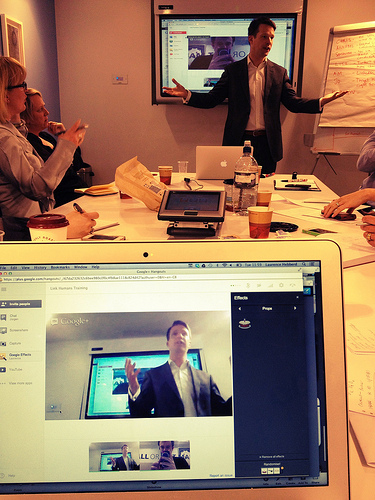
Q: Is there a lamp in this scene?
A: No, there are no lamps.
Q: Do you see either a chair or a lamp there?
A: No, there are no lamps or chairs.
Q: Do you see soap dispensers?
A: No, there are no soap dispensers.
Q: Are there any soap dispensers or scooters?
A: No, there are no soap dispensers or scooters.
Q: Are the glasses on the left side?
A: Yes, the glasses are on the left of the image.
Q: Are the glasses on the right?
A: No, the glasses are on the left of the image.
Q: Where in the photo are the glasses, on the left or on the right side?
A: The glasses are on the left of the image.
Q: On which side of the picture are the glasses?
A: The glasses are on the left of the image.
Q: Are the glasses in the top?
A: Yes, the glasses are in the top of the image.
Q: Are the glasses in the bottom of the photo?
A: No, the glasses are in the top of the image.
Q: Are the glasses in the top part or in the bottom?
A: The glasses are in the top of the image.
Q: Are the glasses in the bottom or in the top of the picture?
A: The glasses are in the top of the image.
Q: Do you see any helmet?
A: No, there are no helmets.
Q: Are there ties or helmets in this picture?
A: No, there are no helmets or ties.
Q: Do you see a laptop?
A: Yes, there is a laptop.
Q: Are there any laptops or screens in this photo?
A: Yes, there is a laptop.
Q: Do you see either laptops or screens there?
A: Yes, there is a laptop.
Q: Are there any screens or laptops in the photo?
A: Yes, there is a laptop.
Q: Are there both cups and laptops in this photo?
A: Yes, there are both a laptop and a cup.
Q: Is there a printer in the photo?
A: No, there are no printers.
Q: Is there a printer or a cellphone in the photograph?
A: No, there are no printers or cell phones.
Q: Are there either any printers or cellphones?
A: No, there are no printers or cellphones.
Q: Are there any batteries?
A: No, there are no batteries.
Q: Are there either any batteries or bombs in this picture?
A: No, there are no batteries or bombs.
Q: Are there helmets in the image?
A: No, there are no helmets.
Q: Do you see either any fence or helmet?
A: No, there are no helmets or fences.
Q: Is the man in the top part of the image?
A: Yes, the man is in the top of the image.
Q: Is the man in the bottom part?
A: No, the man is in the top of the image.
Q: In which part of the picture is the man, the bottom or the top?
A: The man is in the top of the image.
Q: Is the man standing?
A: Yes, the man is standing.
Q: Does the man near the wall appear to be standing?
A: Yes, the man is standing.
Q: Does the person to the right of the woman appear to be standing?
A: Yes, the man is standing.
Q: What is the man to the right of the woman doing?
A: The man is standing.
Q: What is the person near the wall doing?
A: The man is standing.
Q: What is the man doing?
A: The man is standing.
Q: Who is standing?
A: The man is standing.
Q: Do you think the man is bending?
A: No, the man is standing.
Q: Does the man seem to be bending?
A: No, the man is standing.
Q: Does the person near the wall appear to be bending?
A: No, the man is standing.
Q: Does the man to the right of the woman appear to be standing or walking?
A: The man is standing.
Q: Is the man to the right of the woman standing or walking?
A: The man is standing.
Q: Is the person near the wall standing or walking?
A: The man is standing.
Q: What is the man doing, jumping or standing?
A: The man is standing.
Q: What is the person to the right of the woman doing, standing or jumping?
A: The man is standing.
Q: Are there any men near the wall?
A: Yes, there is a man near the wall.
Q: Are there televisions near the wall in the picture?
A: No, there is a man near the wall.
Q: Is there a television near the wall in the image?
A: No, there is a man near the wall.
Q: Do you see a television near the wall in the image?
A: No, there is a man near the wall.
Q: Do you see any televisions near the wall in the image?
A: No, there is a man near the wall.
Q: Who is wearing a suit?
A: The man is wearing a suit.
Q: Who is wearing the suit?
A: The man is wearing a suit.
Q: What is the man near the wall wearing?
A: The man is wearing a suit.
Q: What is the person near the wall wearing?
A: The man is wearing a suit.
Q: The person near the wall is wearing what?
A: The man is wearing a suit.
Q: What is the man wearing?
A: The man is wearing a suit.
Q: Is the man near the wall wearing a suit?
A: Yes, the man is wearing a suit.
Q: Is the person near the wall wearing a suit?
A: Yes, the man is wearing a suit.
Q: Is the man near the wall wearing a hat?
A: No, the man is wearing a suit.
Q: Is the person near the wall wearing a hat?
A: No, the man is wearing a suit.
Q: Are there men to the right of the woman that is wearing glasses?
A: Yes, there is a man to the right of the woman.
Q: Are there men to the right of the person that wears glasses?
A: Yes, there is a man to the right of the woman.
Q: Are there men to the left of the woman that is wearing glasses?
A: No, the man is to the right of the woman.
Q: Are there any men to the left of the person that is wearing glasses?
A: No, the man is to the right of the woman.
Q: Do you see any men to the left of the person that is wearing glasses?
A: No, the man is to the right of the woman.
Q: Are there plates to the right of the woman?
A: No, there is a man to the right of the woman.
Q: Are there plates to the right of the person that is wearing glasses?
A: No, there is a man to the right of the woman.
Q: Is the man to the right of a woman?
A: Yes, the man is to the right of a woman.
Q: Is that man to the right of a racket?
A: No, the man is to the right of a woman.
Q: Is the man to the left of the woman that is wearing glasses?
A: No, the man is to the right of the woman.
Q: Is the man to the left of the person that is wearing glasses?
A: No, the man is to the right of the woman.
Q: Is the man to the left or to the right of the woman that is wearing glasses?
A: The man is to the right of the woman.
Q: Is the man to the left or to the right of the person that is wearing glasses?
A: The man is to the right of the woman.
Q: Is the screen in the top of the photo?
A: Yes, the screen is in the top of the image.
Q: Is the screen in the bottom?
A: No, the screen is in the top of the image.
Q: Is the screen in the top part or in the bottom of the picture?
A: The screen is in the top of the image.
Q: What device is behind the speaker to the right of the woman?
A: The device is a screen.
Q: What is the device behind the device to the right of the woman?
A: The device is a screen.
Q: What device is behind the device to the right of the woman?
A: The device is a screen.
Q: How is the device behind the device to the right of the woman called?
A: The device is a screen.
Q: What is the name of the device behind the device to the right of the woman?
A: The device is a screen.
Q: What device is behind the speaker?
A: The device is a screen.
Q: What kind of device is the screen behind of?
A: The screen is behind the speaker.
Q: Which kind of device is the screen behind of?
A: The screen is behind the speaker.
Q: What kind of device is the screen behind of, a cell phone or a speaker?
A: The screen is behind a speaker.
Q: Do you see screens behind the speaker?
A: Yes, there is a screen behind the speaker.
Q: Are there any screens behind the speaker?
A: Yes, there is a screen behind the speaker.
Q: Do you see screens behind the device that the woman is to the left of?
A: Yes, there is a screen behind the speaker.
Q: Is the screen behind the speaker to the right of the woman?
A: Yes, the screen is behind the speaker.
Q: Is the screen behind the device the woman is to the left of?
A: Yes, the screen is behind the speaker.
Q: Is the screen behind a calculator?
A: No, the screen is behind the speaker.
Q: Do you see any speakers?
A: Yes, there is a speaker.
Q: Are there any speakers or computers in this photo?
A: Yes, there is a speaker.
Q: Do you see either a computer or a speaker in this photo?
A: Yes, there is a speaker.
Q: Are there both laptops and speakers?
A: Yes, there are both a speaker and a laptop.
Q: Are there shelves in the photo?
A: No, there are no shelves.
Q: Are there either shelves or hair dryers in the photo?
A: No, there are no shelves or hair dryers.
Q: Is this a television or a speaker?
A: This is a speaker.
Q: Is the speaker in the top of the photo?
A: Yes, the speaker is in the top of the image.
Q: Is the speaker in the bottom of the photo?
A: No, the speaker is in the top of the image.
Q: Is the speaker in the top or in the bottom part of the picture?
A: The speaker is in the top of the image.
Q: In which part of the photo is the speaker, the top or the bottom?
A: The speaker is in the top of the image.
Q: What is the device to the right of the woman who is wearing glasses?
A: The device is a speaker.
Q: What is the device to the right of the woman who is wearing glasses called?
A: The device is a speaker.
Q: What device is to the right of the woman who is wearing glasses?
A: The device is a speaker.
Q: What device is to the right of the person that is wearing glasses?
A: The device is a speaker.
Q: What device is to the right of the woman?
A: The device is a speaker.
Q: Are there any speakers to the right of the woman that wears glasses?
A: Yes, there is a speaker to the right of the woman.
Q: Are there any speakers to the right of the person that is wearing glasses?
A: Yes, there is a speaker to the right of the woman.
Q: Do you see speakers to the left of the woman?
A: No, the speaker is to the right of the woman.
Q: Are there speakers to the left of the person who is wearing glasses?
A: No, the speaker is to the right of the woman.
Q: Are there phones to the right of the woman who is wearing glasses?
A: No, there is a speaker to the right of the woman.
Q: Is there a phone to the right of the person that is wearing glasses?
A: No, there is a speaker to the right of the woman.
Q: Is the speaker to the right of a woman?
A: Yes, the speaker is to the right of a woman.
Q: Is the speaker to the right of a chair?
A: No, the speaker is to the right of a woman.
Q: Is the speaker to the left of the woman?
A: No, the speaker is to the right of the woman.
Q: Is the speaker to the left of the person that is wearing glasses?
A: No, the speaker is to the right of the woman.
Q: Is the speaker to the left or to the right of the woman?
A: The speaker is to the right of the woman.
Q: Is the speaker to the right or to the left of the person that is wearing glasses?
A: The speaker is to the right of the woman.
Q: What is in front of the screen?
A: The speaker is in front of the screen.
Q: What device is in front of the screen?
A: The device is a speaker.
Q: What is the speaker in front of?
A: The speaker is in front of the screen.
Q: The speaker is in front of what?
A: The speaker is in front of the screen.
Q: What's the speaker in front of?
A: The speaker is in front of the screen.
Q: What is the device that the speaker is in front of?
A: The device is a screen.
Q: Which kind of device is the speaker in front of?
A: The speaker is in front of the screen.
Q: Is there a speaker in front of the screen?
A: Yes, there is a speaker in front of the screen.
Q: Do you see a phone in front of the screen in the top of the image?
A: No, there is a speaker in front of the screen.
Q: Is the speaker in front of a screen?
A: Yes, the speaker is in front of a screen.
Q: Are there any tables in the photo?
A: Yes, there is a table.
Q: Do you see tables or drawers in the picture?
A: Yes, there is a table.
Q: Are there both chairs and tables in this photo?
A: No, there is a table but no chairs.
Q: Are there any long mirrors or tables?
A: Yes, there is a long table.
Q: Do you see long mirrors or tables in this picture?
A: Yes, there is a long table.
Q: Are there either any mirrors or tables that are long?
A: Yes, the table is long.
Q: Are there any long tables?
A: Yes, there is a long table.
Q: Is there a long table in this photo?
A: Yes, there is a long table.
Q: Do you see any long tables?
A: Yes, there is a long table.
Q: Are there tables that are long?
A: Yes, there is a table that is long.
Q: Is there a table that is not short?
A: Yes, there is a long table.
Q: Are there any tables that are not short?
A: Yes, there is a long table.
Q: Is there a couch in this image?
A: No, there are no couches.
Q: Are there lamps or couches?
A: No, there are no couches or lamps.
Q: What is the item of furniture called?
A: The piece of furniture is a table.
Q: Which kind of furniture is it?
A: The piece of furniture is a table.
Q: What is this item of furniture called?
A: This is a table.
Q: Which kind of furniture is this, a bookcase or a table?
A: This is a table.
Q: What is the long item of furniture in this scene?
A: The piece of furniture is a table.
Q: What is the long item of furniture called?
A: The piece of furniture is a table.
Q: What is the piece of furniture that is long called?
A: The piece of furniture is a table.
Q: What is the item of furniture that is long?
A: The piece of furniture is a table.